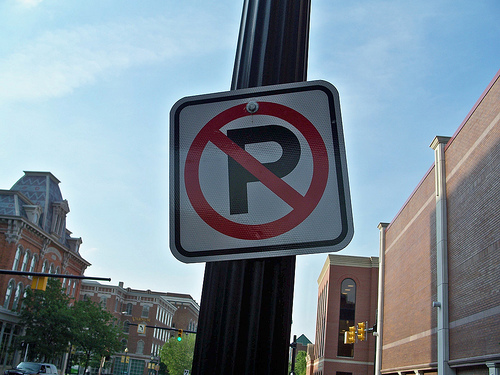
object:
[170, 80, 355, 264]
sign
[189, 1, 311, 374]
pole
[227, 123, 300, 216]
letter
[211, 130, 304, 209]
line`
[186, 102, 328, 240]
circle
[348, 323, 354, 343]
light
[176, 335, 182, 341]
light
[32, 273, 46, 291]
back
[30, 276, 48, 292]
traffic light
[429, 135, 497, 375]
shadow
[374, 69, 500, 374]
brick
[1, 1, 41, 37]
cloud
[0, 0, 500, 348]
sky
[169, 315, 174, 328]
window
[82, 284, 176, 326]
floor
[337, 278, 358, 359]
window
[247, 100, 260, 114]
screw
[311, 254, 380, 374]
building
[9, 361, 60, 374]
vehicle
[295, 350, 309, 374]
tree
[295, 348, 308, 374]
leaves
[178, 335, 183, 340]
green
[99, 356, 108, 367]
flag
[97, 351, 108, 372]
pole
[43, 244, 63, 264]
design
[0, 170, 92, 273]
roof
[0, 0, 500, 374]
daytime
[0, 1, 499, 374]
city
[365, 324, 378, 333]
pole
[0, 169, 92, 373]
building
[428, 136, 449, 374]
column